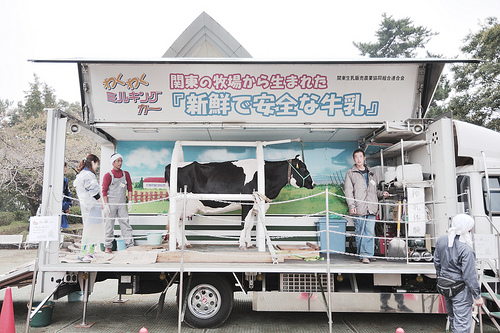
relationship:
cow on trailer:
[161, 150, 311, 257] [24, 121, 427, 319]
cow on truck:
[165, 153, 316, 251] [10, 40, 484, 330]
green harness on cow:
[285, 160, 313, 187] [152, 128, 319, 240]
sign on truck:
[81, 60, 428, 129] [10, 40, 484, 330]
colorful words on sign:
[100, 67, 408, 115] [81, 60, 428, 129]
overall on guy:
[347, 142, 387, 242] [344, 145, 376, 236]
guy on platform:
[101, 152, 134, 255] [44, 244, 447, 274]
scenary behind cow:
[118, 145, 365, 222] [157, 151, 320, 251]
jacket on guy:
[72, 170, 104, 246] [72, 154, 105, 263]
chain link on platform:
[59, 187, 446, 264] [51, 237, 438, 274]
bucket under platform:
[26, 301, 52, 326] [30, 232, 499, 329]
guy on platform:
[344, 149, 389, 263] [26, 236, 453, 278]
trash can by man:
[314, 213, 347, 256] [342, 145, 387, 256]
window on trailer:
[477, 171, 498, 216] [27, 59, 499, 329]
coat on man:
[340, 162, 382, 217] [336, 146, 391, 265]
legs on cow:
[153, 203, 201, 253] [131, 142, 326, 247]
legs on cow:
[237, 209, 257, 251] [157, 151, 320, 251]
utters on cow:
[163, 194, 213, 232] [166, 148, 343, 243]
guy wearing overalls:
[101, 152, 134, 255] [102, 171, 137, 246]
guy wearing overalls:
[344, 149, 389, 263] [102, 171, 137, 246]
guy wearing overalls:
[101, 152, 134, 255] [106, 173, 129, 234]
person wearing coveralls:
[54, 158, 76, 254] [100, 167, 135, 249]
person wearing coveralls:
[72, 150, 112, 262] [100, 167, 135, 249]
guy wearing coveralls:
[101, 152, 134, 255] [100, 167, 135, 249]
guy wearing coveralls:
[344, 149, 389, 263] [100, 167, 135, 249]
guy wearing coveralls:
[433, 214, 484, 333] [100, 167, 135, 249]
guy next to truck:
[433, 214, 484, 333] [10, 40, 484, 330]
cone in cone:
[2, 287, 22, 331] [0, 287, 20, 332]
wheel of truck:
[172, 273, 234, 328] [182, 270, 242, 330]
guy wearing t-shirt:
[433, 214, 484, 333] [431, 206, 475, 252]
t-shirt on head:
[431, 206, 475, 252] [444, 207, 478, 248]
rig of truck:
[17, 46, 437, 331] [10, 40, 484, 330]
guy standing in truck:
[344, 149, 389, 263] [10, 40, 484, 330]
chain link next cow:
[45, 192, 448, 265] [164, 154, 315, 262]